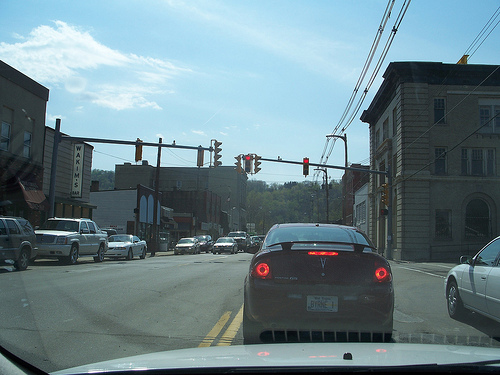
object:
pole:
[252, 157, 389, 176]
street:
[0, 234, 499, 374]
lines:
[197, 308, 233, 350]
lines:
[218, 304, 247, 348]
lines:
[203, 250, 233, 262]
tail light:
[250, 260, 272, 279]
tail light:
[372, 261, 391, 284]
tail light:
[308, 250, 339, 256]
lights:
[43, 119, 392, 259]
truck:
[0, 212, 39, 270]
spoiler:
[266, 241, 378, 254]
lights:
[234, 153, 262, 174]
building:
[78, 183, 163, 256]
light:
[303, 157, 310, 175]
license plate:
[307, 295, 339, 313]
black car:
[242, 223, 394, 348]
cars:
[35, 216, 109, 264]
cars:
[94, 234, 147, 260]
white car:
[444, 233, 499, 321]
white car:
[0, 332, 497, 373]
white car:
[101, 233, 148, 261]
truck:
[28, 216, 109, 264]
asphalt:
[76, 292, 123, 352]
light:
[250, 257, 273, 281]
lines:
[192, 299, 264, 347]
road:
[0, 244, 490, 372]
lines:
[195, 328, 230, 347]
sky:
[2, 0, 500, 185]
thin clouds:
[0, 17, 191, 114]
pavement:
[0, 244, 498, 371]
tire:
[445, 275, 472, 320]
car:
[445, 235, 500, 332]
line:
[197, 304, 246, 350]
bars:
[115, 164, 225, 249]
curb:
[0, 245, 27, 280]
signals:
[234, 154, 261, 175]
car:
[246, 222, 395, 334]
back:
[245, 239, 393, 341]